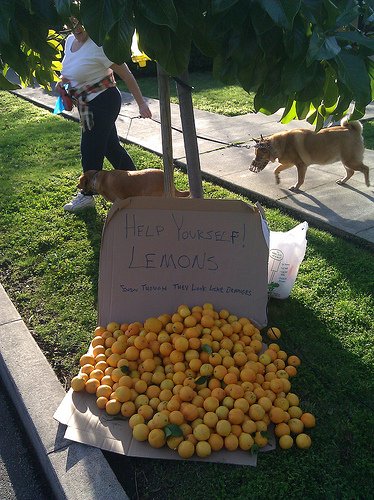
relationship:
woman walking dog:
[53, 12, 152, 216] [71, 163, 196, 216]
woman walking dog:
[53, 12, 152, 216] [244, 115, 370, 196]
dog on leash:
[75, 168, 195, 210] [119, 131, 129, 151]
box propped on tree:
[98, 192, 266, 326] [2, 1, 370, 206]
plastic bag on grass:
[266, 221, 307, 301] [0, 94, 92, 323]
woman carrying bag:
[53, 12, 152, 216] [50, 82, 69, 113]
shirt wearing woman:
[48, 33, 126, 100] [53, 12, 152, 216]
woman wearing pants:
[53, 12, 152, 216] [79, 86, 136, 171]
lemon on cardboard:
[239, 365, 258, 387] [91, 192, 272, 325]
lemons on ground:
[78, 306, 320, 458] [7, 97, 314, 468]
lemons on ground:
[95, 328, 168, 404] [40, 295, 361, 481]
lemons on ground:
[206, 343, 299, 455] [16, 112, 348, 493]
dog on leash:
[75, 168, 195, 210] [100, 106, 144, 171]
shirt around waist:
[60, 79, 126, 108] [62, 79, 133, 112]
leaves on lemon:
[157, 412, 186, 443] [163, 309, 252, 391]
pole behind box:
[171, 52, 207, 194] [98, 192, 266, 326]